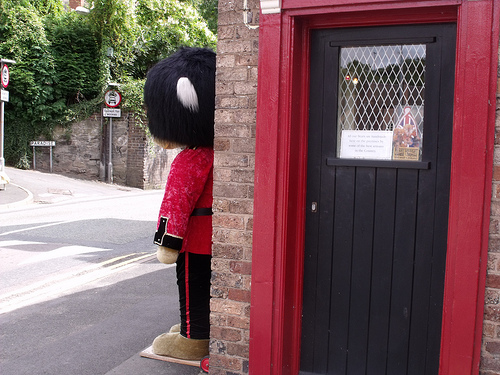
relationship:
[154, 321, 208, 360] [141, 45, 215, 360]
feet on creature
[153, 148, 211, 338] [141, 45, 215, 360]
clothes on creature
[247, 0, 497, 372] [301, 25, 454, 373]
frame on door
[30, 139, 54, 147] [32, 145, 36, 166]
sign on pole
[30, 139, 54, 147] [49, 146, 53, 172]
sign on pole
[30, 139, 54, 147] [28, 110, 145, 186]
sign against a wall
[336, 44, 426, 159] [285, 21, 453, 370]
window on a door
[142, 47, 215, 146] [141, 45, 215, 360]
helmet on a creature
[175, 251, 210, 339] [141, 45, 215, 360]
pants on a creature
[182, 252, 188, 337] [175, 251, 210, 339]
stripe on pants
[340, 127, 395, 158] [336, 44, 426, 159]
notice on window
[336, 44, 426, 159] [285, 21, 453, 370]
window on door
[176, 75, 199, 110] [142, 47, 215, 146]
fur on helmet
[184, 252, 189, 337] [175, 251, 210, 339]
stripe on pants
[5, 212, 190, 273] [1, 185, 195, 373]
shadow on cement